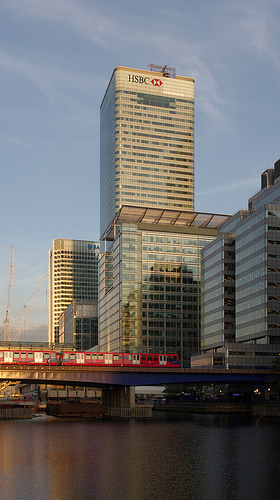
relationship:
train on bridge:
[4, 345, 170, 362] [0, 364, 244, 418]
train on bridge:
[0, 348, 181, 371] [2, 341, 280, 388]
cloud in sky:
[0, 0, 280, 328] [1, 1, 271, 338]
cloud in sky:
[0, 0, 280, 328] [1, 0, 279, 69]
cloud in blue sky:
[0, 0, 280, 328] [8, 14, 90, 201]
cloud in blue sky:
[0, 0, 280, 328] [0, 0, 280, 331]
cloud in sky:
[0, 0, 280, 328] [3, 8, 273, 210]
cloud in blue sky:
[0, 0, 280, 328] [165, 19, 276, 87]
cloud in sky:
[0, 0, 280, 328] [5, 166, 54, 227]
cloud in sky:
[0, 0, 280, 328] [18, 10, 264, 196]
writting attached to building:
[126, 73, 169, 87] [90, 64, 206, 214]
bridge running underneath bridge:
[45, 400, 102, 417] [0, 363, 278, 419]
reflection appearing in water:
[139, 407, 257, 430] [0, 409, 277, 498]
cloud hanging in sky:
[0, 0, 280, 328] [1, 1, 271, 338]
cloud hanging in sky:
[3, 239, 49, 293] [1, 1, 271, 338]